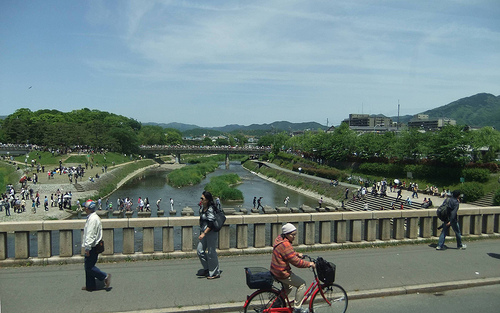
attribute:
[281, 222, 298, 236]
hat — white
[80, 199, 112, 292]
man — walking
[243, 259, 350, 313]
bike — red, bright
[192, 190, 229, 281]
woman — walking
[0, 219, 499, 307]
bride — high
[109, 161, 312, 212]
water — long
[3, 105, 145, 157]
trees — green, big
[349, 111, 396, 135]
building — tall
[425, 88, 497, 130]
hill — green, distant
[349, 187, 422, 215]
steps — cement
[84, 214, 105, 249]
shirt — white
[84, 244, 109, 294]
pants — black